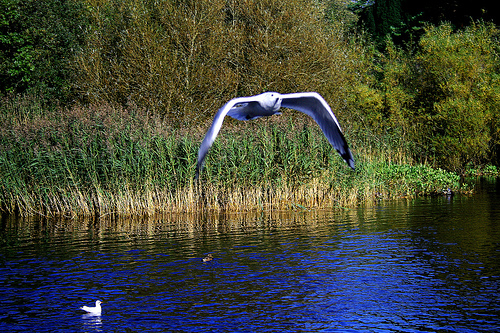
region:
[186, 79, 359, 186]
bird flying above water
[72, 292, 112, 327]
white bird floating on water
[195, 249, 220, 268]
brown bird floating on water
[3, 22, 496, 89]
trees with green foliage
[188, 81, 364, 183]
one white bird flying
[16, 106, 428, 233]
green rushes next to water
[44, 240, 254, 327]
two water fowl in water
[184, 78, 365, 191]
bird with wings open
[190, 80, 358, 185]
white bird in flight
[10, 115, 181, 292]
foliage and water at shoreline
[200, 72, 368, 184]
this is a bird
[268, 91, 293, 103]
the bird is white in color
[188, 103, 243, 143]
this is the wing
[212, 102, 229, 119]
the wing is white in color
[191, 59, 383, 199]
the bird is on air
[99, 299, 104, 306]
this is the beak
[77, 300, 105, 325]
the bird is on water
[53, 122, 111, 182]
this is a grass area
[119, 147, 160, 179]
the grass is green in color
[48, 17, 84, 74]
this is a tree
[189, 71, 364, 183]
this is a bird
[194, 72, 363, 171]
the bird is flying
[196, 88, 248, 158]
this is the wing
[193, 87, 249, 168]
the wing is folded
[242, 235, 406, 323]
this is the water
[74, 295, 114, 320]
the bird is swimming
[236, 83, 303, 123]
the bird is white in color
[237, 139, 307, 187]
these are the grass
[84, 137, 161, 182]
the grass are green in color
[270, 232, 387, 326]
the water is blue in color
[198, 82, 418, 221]
a bird in air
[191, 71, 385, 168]
the bird is moving horizontaly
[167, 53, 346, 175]
the bird is above the water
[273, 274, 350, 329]
water is blue in color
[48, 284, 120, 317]
bird is swimimng in water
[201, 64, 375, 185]
bird is blue white in color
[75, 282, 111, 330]
bird is white in color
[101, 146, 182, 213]
plants are in water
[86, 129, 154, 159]
plants are green in color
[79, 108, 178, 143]
plants have green tops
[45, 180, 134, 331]
a white sea gull swimming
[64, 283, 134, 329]
a white sea gull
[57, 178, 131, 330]
a white sea gull near the shore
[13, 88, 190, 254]
rushes on the shoreline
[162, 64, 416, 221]
a seagull in flight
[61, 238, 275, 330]
a seagull and a duck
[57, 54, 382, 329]
two seagulls and a duck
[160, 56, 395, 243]
a sea gull in mid-flight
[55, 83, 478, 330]
birds at the shoreline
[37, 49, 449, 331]
three birds in nature